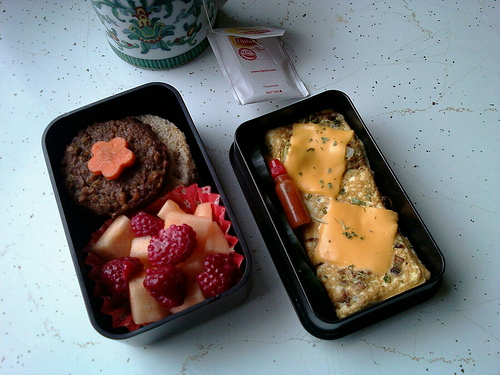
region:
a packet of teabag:
[201, 17, 336, 152]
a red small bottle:
[252, 153, 319, 231]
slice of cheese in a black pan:
[278, 117, 353, 194]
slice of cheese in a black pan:
[316, 182, 398, 277]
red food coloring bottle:
[260, 153, 312, 233]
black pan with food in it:
[218, 83, 453, 348]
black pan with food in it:
[38, 78, 258, 345]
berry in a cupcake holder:
[145, 219, 196, 267]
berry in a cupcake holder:
[193, 255, 239, 299]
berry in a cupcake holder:
[99, 253, 137, 292]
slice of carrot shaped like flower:
[90, 137, 140, 182]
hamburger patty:
[56, 117, 177, 213]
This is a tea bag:
[199, 21, 276, 108]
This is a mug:
[120, 33, 205, 78]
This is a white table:
[400, 51, 497, 254]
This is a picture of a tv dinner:
[279, 129, 393, 332]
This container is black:
[138, 95, 254, 152]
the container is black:
[37, 79, 265, 371]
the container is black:
[232, 99, 425, 366]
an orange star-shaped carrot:
[80, 135, 143, 190]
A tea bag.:
[209, 27, 311, 107]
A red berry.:
[143, 223, 194, 266]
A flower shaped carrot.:
[85, 135, 135, 176]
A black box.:
[41, 81, 262, 346]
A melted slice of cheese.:
[310, 197, 398, 274]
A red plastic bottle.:
[270, 157, 311, 227]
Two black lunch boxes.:
[37, 81, 453, 342]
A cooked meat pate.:
[65, 118, 170, 210]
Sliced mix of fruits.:
[87, 190, 233, 331]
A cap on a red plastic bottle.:
[267, 157, 284, 174]